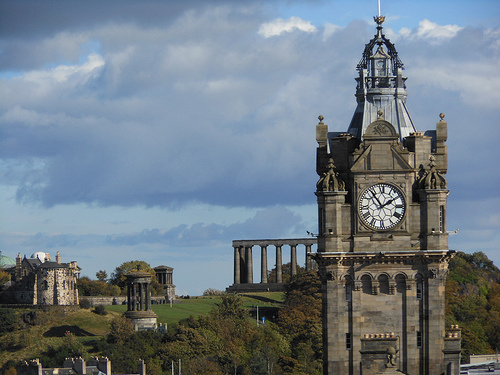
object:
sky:
[1, 0, 498, 299]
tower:
[309, 2, 458, 375]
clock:
[358, 182, 408, 233]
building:
[230, 237, 318, 291]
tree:
[285, 273, 323, 332]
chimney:
[170, 361, 175, 375]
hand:
[369, 189, 384, 206]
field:
[104, 293, 285, 321]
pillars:
[121, 274, 156, 319]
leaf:
[279, 314, 303, 326]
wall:
[84, 295, 166, 302]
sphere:
[318, 115, 324, 120]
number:
[377, 185, 385, 193]